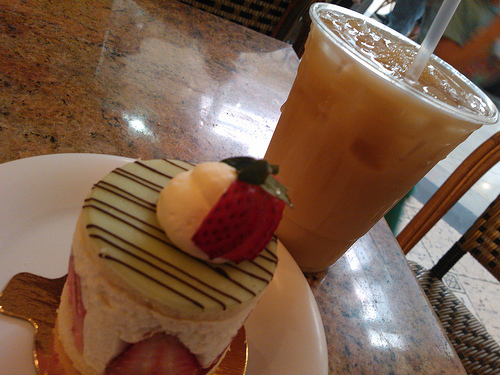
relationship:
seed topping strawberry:
[209, 226, 217, 235] [189, 152, 294, 269]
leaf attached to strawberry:
[260, 171, 295, 210] [189, 152, 294, 269]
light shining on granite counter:
[199, 94, 277, 161] [0, 0, 499, 375]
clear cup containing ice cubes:
[245, 3, 499, 272] [245, 3, 499, 275]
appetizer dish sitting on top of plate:
[48, 153, 293, 375] [5, 155, 340, 373]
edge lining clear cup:
[306, 2, 485, 125] [245, 3, 499, 272]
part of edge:
[157, 294, 198, 330] [155, 294, 205, 324]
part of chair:
[427, 245, 466, 299] [431, 240, 460, 281]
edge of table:
[400, 272, 432, 332] [357, 248, 463, 373]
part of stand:
[426, 245, 466, 299] [425, 245, 466, 294]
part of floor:
[430, 230, 447, 260] [431, 224, 449, 258]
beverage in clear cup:
[257, 0, 499, 276] [245, 2, 498, 283]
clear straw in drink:
[395, 2, 463, 78] [255, 0, 492, 300]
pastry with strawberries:
[35, 139, 285, 371] [176, 144, 282, 258]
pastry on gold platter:
[51, 144, 286, 371] [5, 230, 255, 373]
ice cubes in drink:
[308, 5, 493, 122] [239, 5, 498, 296]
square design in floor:
[417, 234, 479, 311] [382, 100, 500, 346]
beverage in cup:
[315, 17, 391, 215] [265, 6, 485, 302]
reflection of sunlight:
[111, 3, 302, 176] [103, 19, 302, 150]